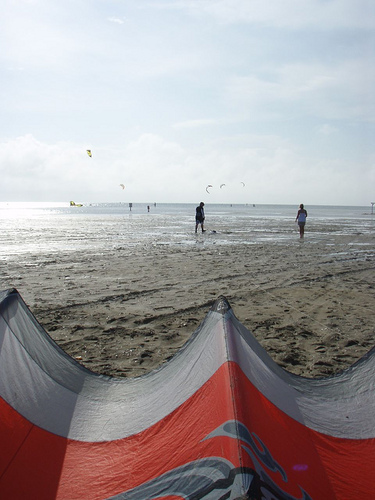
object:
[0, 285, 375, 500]
tarp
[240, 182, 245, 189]
kite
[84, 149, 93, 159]
kite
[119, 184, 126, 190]
kite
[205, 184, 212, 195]
kite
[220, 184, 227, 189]
kite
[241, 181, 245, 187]
kite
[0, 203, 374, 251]
water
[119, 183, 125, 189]
parasail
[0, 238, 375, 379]
tracks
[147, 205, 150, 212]
sign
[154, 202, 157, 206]
sign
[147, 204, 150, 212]
person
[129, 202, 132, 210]
person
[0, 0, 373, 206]
blue sky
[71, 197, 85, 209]
sports participant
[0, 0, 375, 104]
clouds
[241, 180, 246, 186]
seagull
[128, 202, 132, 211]
sign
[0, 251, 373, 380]
tire tracks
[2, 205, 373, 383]
beach sand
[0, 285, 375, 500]
hang glider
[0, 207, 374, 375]
beach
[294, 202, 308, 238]
people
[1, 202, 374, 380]
beach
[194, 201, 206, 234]
man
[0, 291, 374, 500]
sail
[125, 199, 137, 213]
sign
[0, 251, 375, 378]
feet prints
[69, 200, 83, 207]
kite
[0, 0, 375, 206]
sky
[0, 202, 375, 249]
ocean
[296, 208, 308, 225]
shirt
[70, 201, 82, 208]
equipment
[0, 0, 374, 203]
air